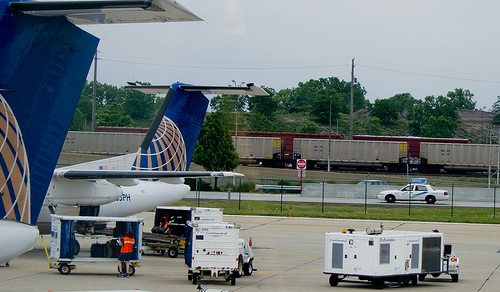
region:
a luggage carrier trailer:
[38, 203, 150, 276]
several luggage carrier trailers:
[179, 200, 246, 281]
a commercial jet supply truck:
[312, 208, 464, 283]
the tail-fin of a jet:
[131, 77, 213, 168]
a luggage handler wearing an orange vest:
[109, 223, 137, 275]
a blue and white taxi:
[377, 175, 450, 210]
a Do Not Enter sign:
[291, 150, 313, 180]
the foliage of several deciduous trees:
[233, 70, 492, 134]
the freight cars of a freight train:
[73, 125, 498, 172]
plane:
[85, 69, 243, 201]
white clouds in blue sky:
[391, 13, 419, 44]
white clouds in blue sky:
[367, 2, 399, 44]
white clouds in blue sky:
[261, 16, 325, 44]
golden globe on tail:
[133, 114, 188, 171]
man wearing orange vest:
[118, 228, 135, 278]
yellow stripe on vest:
[120, 237, 138, 245]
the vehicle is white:
[321, 218, 463, 290]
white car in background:
[378, 176, 452, 206]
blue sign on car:
[405, 174, 430, 185]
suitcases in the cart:
[86, 239, 123, 256]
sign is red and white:
[297, 154, 307, 171]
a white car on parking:
[374, 178, 454, 208]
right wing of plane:
[62, 159, 244, 187]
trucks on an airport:
[145, 197, 262, 289]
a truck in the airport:
[310, 212, 463, 288]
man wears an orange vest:
[115, 225, 136, 277]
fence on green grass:
[195, 173, 496, 223]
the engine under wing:
[48, 180, 128, 210]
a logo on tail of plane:
[131, 84, 211, 169]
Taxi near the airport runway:
[384, 178, 455, 207]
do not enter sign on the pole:
[292, 152, 312, 172]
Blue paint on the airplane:
[118, 63, 272, 182]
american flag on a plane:
[93, 160, 112, 173]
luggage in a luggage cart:
[89, 235, 129, 259]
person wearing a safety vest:
[112, 231, 135, 267]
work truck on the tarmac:
[316, 200, 472, 289]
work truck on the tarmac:
[184, 209, 261, 286]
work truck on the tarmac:
[140, 190, 262, 285]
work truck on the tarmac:
[326, 211, 466, 283]